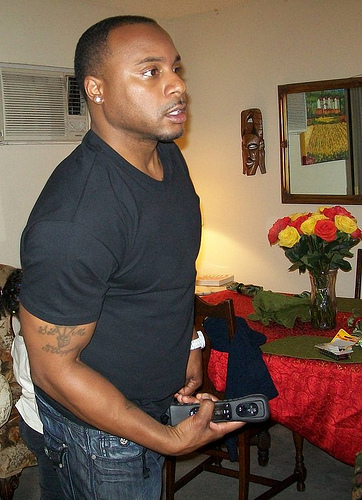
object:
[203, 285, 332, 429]
table cloth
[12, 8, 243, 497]
man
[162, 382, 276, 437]
wii remote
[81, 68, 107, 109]
earring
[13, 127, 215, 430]
shirt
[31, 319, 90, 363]
tatto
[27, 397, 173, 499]
jeans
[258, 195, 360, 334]
flowers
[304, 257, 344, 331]
vase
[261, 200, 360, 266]
roses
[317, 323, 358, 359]
batteries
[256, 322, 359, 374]
green placema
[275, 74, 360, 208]
mirror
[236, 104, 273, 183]
mask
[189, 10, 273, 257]
wall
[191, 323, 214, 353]
watch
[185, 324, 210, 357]
wrist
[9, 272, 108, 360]
bicep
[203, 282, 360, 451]
table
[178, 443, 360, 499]
flooring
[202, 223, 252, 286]
light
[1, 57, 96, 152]
conditioner unit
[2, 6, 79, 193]
wall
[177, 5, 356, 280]
wall